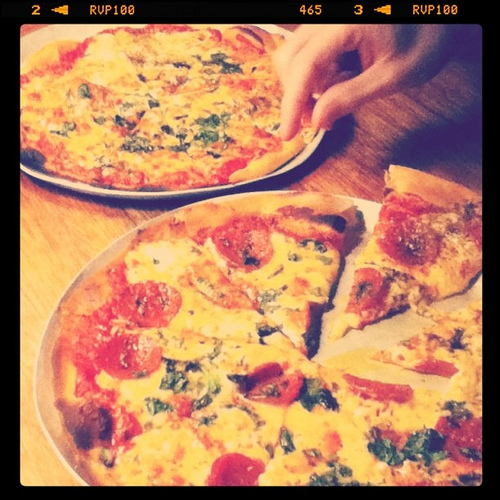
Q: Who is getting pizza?
A: Person.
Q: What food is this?
A: Pizza.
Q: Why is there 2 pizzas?
A: Different Toppings.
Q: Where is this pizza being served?
A: On a table.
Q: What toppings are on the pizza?
A: Cheese, pepperoni, spinich.